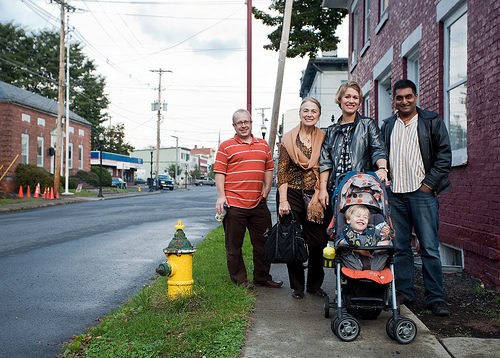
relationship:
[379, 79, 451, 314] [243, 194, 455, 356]
man are standing on sidewalk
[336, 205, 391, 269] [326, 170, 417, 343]
boy sitting in stroller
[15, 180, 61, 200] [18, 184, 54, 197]
cluster of cones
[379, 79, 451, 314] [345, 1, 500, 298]
man are standing by building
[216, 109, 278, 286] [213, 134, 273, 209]
man wearing shirt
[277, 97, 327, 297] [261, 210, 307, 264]
woman holding bag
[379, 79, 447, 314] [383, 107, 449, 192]
man has jacket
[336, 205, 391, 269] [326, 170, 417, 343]
baby sitting in stroller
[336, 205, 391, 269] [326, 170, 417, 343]
baby in stroller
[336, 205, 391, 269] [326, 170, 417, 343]
boy in stroller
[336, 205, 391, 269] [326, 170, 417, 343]
toddler sitting in stroller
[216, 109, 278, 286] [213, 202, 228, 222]
man holding bottle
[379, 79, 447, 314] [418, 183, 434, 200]
man has hand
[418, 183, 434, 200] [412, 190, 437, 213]
hand in pocket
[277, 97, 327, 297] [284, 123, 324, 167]
woman has scarf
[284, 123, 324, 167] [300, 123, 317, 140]
scarf around neck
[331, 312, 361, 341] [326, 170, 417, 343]
wheel of stroller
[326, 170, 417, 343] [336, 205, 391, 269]
stroller for baby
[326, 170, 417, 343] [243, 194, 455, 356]
stroller on sidewalk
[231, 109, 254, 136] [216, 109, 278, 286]
head of man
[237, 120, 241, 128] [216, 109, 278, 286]
eye of man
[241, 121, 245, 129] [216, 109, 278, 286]
nose of man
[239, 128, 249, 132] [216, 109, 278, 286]
mouth of man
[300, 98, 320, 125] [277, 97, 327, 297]
head of woman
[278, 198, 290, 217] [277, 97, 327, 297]
hand of woman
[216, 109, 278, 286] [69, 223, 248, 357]
man standing on grass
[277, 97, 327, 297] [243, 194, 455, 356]
woman standing on sidewalk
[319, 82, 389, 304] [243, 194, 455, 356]
woman standing on sidewalk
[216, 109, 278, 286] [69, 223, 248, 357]
man standing in grass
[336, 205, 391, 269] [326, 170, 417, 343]
child in stroller